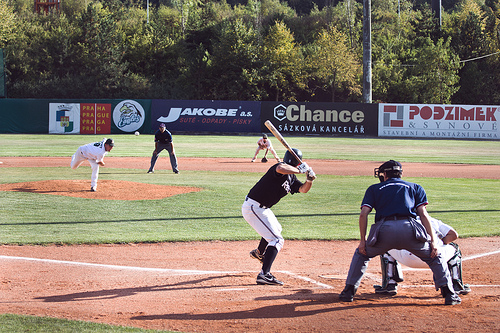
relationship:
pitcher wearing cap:
[70, 137, 115, 193] [103, 137, 115, 150]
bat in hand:
[250, 109, 321, 185] [297, 162, 310, 176]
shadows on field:
[29, 266, 272, 306] [0, 131, 499, 332]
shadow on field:
[124, 297, 454, 323] [0, 131, 499, 332]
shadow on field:
[250, 284, 446, 304] [0, 131, 499, 332]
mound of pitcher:
[0, 174, 191, 206] [70, 137, 115, 193]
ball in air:
[127, 122, 147, 139] [122, 50, 243, 163]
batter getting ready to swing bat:
[243, 119, 316, 284] [265, 118, 316, 179]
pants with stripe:
[240, 195, 284, 252] [250, 202, 279, 245]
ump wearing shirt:
[339, 159, 461, 306] [360, 177, 427, 219]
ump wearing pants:
[339, 159, 461, 306] [345, 215, 452, 290]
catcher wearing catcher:
[371, 203, 474, 299] [370, 214, 471, 297]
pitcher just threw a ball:
[53, 120, 114, 189] [126, 127, 144, 139]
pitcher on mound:
[70, 137, 115, 193] [6, 176, 172, 208]